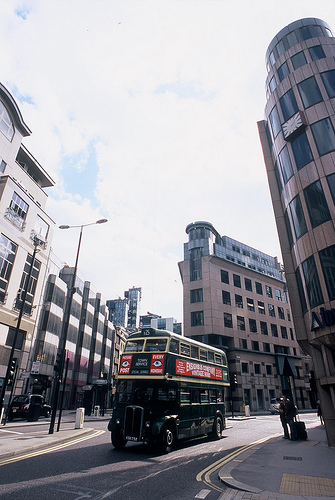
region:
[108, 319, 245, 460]
black double decker bus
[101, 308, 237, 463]
black double decker bus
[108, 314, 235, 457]
black double decker bus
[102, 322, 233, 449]
black double decker bus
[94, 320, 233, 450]
black double decker bus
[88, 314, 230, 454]
black double decker bus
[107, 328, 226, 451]
double decker bus driving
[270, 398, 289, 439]
man looking at his phone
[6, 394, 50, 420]
black car parked on the street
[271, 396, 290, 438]
man standing on a sidewalk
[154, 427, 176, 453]
wheels spinning around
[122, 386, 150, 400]
driver driving a bus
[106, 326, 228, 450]
bus carrying passengers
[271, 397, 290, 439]
man reading his phone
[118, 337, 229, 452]
the bus is double decker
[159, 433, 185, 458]
the wheel is black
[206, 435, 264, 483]
the lines are golden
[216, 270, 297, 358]
windows on the building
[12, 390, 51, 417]
the car is parked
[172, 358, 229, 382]
the sign is red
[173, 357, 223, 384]
sign on the bus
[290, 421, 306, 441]
the suitcase is black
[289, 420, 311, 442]
suitcase on the sidewalk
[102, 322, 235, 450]
A double decker bus.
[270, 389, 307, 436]
A person standing with luggage.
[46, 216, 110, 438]
A tall street light.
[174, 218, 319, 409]
A large angled building.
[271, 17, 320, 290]
A very tall building with the clock on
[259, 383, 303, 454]
People waiting to get on the bus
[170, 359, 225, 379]
Red and white sing on the bus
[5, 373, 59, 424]
A old black car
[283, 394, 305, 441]
A man with a suitcase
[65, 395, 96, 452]
A white mailbox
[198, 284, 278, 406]
A tall building with lots of windows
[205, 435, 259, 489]
Yellow lines painted on the road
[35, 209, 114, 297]
To streetlights in the middle of the road